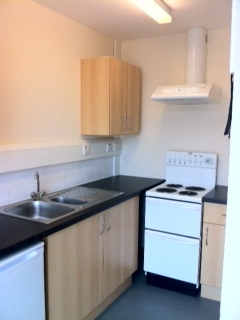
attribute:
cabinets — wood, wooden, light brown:
[80, 56, 141, 136]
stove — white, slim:
[143, 149, 219, 297]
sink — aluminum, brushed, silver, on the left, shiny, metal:
[1, 198, 82, 225]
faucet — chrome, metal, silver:
[30, 171, 45, 201]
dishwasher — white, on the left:
[1, 242, 47, 319]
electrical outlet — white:
[106, 143, 114, 155]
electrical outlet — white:
[83, 144, 91, 156]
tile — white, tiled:
[1, 138, 120, 209]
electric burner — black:
[157, 187, 178, 194]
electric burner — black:
[180, 191, 198, 198]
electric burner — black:
[166, 182, 184, 189]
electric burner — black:
[185, 185, 205, 192]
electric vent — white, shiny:
[150, 27, 222, 104]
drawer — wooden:
[203, 201, 227, 225]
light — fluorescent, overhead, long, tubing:
[133, 0, 173, 25]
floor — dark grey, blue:
[91, 246, 221, 319]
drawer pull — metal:
[220, 212, 226, 219]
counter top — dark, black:
[1, 174, 165, 258]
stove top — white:
[144, 179, 214, 203]